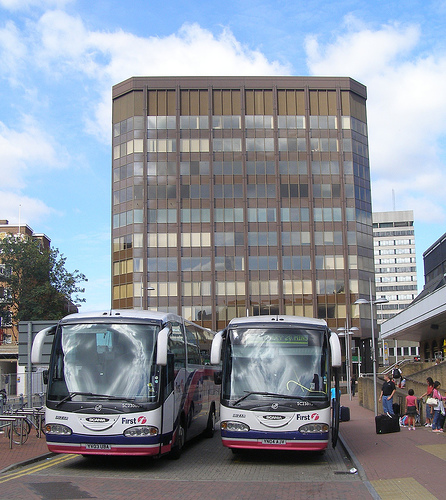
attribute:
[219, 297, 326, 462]
passenger bus — white 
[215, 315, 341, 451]
bus — white, purple, pink 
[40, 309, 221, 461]
bus — white 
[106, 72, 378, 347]
building — brown 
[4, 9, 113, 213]
clouds — white 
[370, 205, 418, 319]
building — white 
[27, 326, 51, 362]
mirror — white 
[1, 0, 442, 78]
clouds — white 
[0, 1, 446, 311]
sky — blue 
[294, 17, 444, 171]
cloud — white 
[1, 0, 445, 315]
clouds — white 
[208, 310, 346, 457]
bus — white , pink , blue 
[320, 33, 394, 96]
clouds — white 